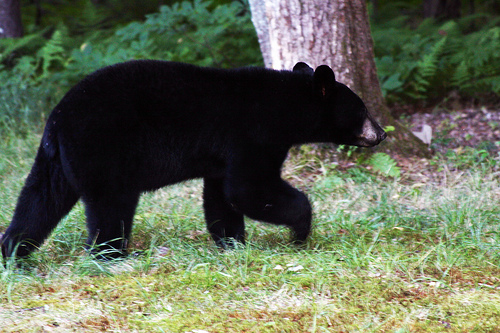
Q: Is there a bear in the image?
A: Yes, there is a bear.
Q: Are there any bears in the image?
A: Yes, there is a bear.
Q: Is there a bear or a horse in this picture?
A: Yes, there is a bear.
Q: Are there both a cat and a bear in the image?
A: No, there is a bear but no cats.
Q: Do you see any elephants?
A: No, there are no elephants.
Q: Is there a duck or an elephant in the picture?
A: No, there are no elephants or ducks.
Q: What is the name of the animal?
A: The animal is a bear.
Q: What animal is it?
A: The animal is a bear.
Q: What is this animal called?
A: This is a bear.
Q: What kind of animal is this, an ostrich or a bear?
A: This is a bear.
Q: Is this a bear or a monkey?
A: This is a bear.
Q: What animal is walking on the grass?
A: The bear is walking on the grass.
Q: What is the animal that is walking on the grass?
A: The animal is a bear.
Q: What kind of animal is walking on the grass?
A: The animal is a bear.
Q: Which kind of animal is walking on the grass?
A: The animal is a bear.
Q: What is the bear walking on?
A: The bear is walking on the grass.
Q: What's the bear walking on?
A: The bear is walking on the grass.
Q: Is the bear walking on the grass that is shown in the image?
A: Yes, the bear is walking on the grass.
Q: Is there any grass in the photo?
A: Yes, there is grass.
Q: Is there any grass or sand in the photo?
A: Yes, there is grass.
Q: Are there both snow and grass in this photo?
A: No, there is grass but no snow.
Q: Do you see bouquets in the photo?
A: No, there are no bouquets.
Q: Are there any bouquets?
A: No, there are no bouquets.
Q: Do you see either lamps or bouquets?
A: No, there are no bouquets or lamps.